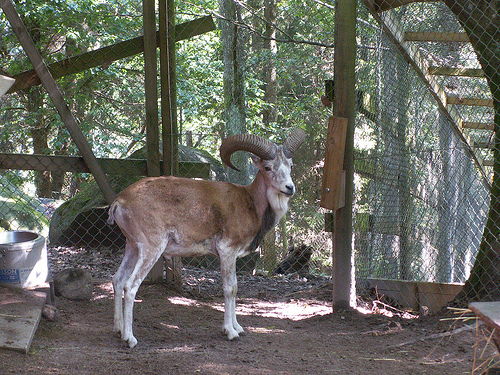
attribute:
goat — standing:
[105, 128, 293, 348]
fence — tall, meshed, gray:
[8, 12, 499, 297]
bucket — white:
[0, 228, 43, 304]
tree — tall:
[214, 3, 254, 191]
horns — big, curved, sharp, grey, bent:
[216, 119, 306, 162]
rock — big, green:
[54, 133, 216, 245]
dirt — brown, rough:
[7, 272, 478, 375]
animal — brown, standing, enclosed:
[114, 144, 293, 316]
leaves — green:
[12, 6, 325, 154]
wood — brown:
[18, 156, 206, 174]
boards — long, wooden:
[0, 149, 203, 177]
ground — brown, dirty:
[3, 253, 490, 372]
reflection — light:
[207, 291, 376, 324]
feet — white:
[110, 293, 259, 349]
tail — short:
[96, 201, 128, 229]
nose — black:
[282, 184, 298, 192]